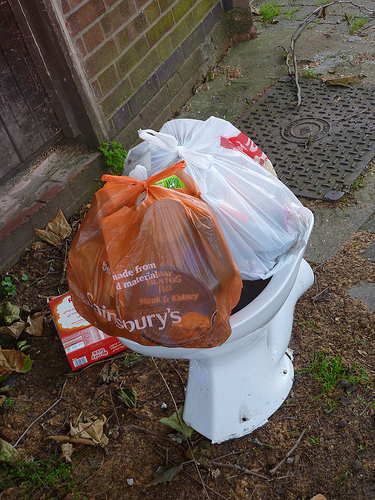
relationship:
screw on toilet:
[238, 414, 248, 422] [38, 194, 334, 391]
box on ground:
[34, 280, 131, 375] [11, 275, 128, 425]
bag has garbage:
[121, 114, 311, 279] [66, 112, 309, 352]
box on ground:
[47, 290, 131, 371] [7, 265, 139, 432]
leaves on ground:
[1, 208, 109, 499] [0, 0, 371, 495]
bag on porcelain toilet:
[65, 159, 242, 347] [116, 206, 318, 444]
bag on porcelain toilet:
[121, 114, 311, 279] [116, 206, 318, 444]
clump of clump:
[347, 12, 372, 36] [257, 0, 278, 24]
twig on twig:
[277, 0, 373, 109] [12, 369, 66, 445]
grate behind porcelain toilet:
[233, 71, 373, 207] [116, 206, 318, 444]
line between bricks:
[75, 11, 107, 35] [60, 1, 246, 154]